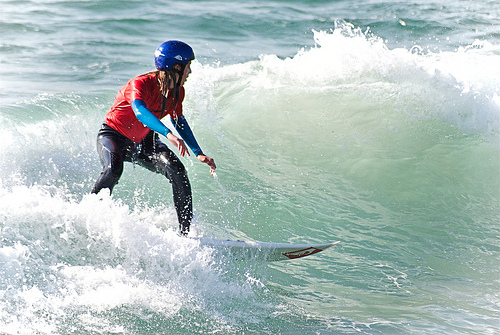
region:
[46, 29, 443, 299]
a young woman surfs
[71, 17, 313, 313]
the surfer is wearing a blue helmet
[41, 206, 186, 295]
white wave crash at the surfer's feet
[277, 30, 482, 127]
waves roll violently towards a surfer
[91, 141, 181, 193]
black pants cover the surfer's legs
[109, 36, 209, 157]
a red shirt with blue sleeves clings to the woman's body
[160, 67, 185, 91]
a black strap secures the helmet to the surfer's head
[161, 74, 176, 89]
wet brown hair sticks the the surfer's neck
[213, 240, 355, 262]
a white surfboard with a red logo supports the surfer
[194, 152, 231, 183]
water drips from the surfer's hand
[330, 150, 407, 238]
the water is blue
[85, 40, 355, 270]
the woman is surfing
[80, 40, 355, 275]
the woman is using a skateboard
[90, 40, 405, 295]
the woman has a helmet on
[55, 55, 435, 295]
waves are in the water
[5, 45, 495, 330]
it is sunny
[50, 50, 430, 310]
the woman is wet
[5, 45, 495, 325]
it is an outdoor scene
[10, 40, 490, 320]
it is in a waterbody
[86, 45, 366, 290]
the woman has black pants on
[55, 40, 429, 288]
surfer riding a wave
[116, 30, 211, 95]
surfer wearing blue helmet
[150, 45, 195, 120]
surfer with long and dark wet hair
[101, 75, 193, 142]
surfer wearing red top with blue sleeves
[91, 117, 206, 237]
surfer wearing shiny black pants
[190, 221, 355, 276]
front of surfboard has red graphic on underside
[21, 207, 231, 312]
rough splashing water on surfer's side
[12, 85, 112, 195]
wall of smooth water behind surfer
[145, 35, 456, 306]
surfer on edge of sloped water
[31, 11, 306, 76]
calmer water behind surfer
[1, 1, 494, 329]
blue green waves splashing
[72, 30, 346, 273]
surfer on wave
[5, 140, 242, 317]
water splashing around surfer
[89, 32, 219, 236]
surfer in red blue and black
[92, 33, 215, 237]
surfer in red t-shirt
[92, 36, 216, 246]
surfer in blue helmet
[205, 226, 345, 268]
red and white surfboard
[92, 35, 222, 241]
surfer in black pants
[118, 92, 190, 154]
light blue arm covering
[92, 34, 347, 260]
surfer on red and white board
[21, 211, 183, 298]
water is splashing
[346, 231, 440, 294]
water is blue in color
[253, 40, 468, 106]
waves are white in color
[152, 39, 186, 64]
helmet is blue in color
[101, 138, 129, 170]
pant is black in color.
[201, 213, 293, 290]
surfing board is white in color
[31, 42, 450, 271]
daytime picture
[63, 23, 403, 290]
one boy is surfing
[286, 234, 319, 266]
logo is red color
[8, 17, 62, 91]
sunlight reflection